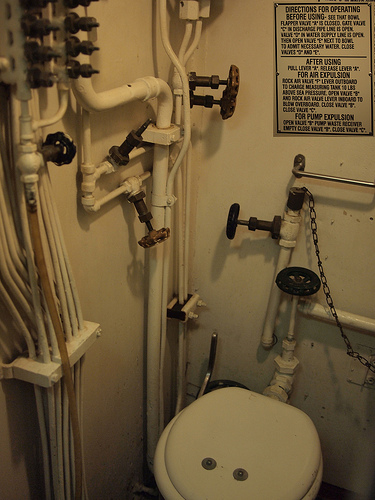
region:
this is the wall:
[188, 143, 247, 188]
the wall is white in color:
[211, 140, 268, 188]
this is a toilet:
[161, 389, 324, 491]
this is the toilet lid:
[212, 401, 275, 429]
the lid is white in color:
[218, 403, 276, 455]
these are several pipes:
[159, 97, 182, 208]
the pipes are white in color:
[145, 301, 164, 356]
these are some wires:
[38, 396, 70, 490]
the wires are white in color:
[36, 399, 65, 453]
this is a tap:
[276, 262, 308, 353]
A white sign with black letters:
[253, 4, 370, 141]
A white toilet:
[116, 355, 322, 498]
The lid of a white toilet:
[165, 373, 329, 497]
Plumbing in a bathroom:
[28, 35, 275, 327]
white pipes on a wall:
[17, 133, 225, 382]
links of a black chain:
[306, 219, 336, 297]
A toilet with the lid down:
[141, 357, 333, 497]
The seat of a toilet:
[153, 430, 176, 490]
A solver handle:
[189, 308, 227, 403]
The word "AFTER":
[297, 52, 325, 68]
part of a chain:
[323, 319, 360, 358]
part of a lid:
[252, 414, 289, 439]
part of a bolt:
[232, 468, 253, 481]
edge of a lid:
[156, 451, 179, 482]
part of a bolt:
[275, 346, 296, 373]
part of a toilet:
[238, 427, 279, 477]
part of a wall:
[100, 388, 130, 427]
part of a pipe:
[135, 365, 163, 413]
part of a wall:
[322, 425, 351, 474]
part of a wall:
[102, 405, 142, 443]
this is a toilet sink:
[177, 402, 302, 489]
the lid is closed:
[179, 410, 307, 489]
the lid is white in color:
[175, 413, 304, 480]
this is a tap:
[278, 263, 321, 306]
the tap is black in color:
[278, 260, 319, 303]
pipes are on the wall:
[146, 248, 187, 294]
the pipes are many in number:
[7, 250, 72, 315]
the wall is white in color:
[97, 229, 132, 289]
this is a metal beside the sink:
[197, 326, 225, 379]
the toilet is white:
[164, 384, 320, 498]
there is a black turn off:
[271, 266, 313, 291]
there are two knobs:
[215, 64, 239, 116]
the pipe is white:
[75, 81, 170, 124]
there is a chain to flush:
[323, 308, 362, 369]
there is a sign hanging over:
[285, 1, 369, 129]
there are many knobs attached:
[24, 0, 99, 80]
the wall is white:
[178, 129, 258, 168]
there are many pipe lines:
[32, 367, 92, 492]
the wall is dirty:
[306, 338, 354, 431]